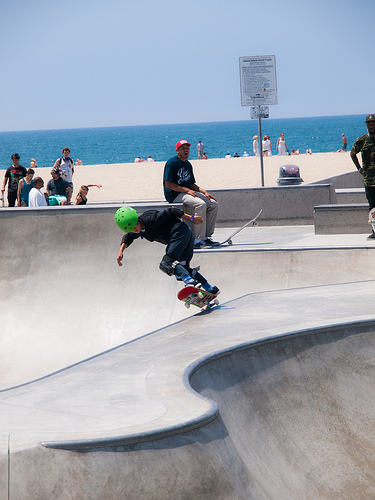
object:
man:
[162, 139, 220, 250]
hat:
[175, 139, 191, 151]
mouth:
[184, 152, 189, 156]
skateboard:
[199, 207, 263, 250]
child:
[113, 203, 220, 296]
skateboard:
[176, 286, 220, 313]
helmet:
[114, 205, 139, 233]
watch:
[189, 215, 195, 223]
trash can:
[270, 157, 302, 185]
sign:
[238, 48, 279, 108]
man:
[341, 132, 347, 152]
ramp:
[0, 209, 374, 387]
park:
[0, 165, 373, 498]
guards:
[159, 254, 178, 276]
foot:
[202, 236, 219, 246]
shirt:
[162, 156, 196, 204]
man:
[349, 112, 374, 241]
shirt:
[350, 131, 375, 187]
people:
[28, 176, 48, 207]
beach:
[0, 148, 374, 207]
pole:
[258, 116, 265, 187]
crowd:
[219, 129, 310, 163]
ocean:
[0, 112, 375, 170]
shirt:
[120, 205, 186, 248]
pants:
[159, 221, 208, 285]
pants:
[172, 192, 219, 240]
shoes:
[193, 238, 213, 249]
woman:
[262, 135, 271, 157]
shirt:
[262, 140, 271, 151]